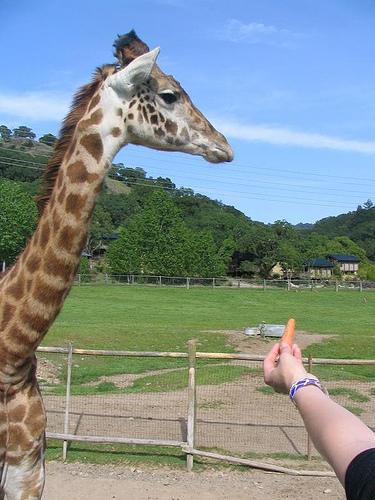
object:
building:
[325, 253, 362, 274]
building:
[303, 256, 335, 277]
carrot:
[278, 318, 295, 354]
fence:
[34, 345, 374, 476]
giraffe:
[0, 28, 234, 499]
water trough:
[244, 321, 286, 338]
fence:
[75, 274, 374, 293]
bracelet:
[289, 377, 328, 408]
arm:
[262, 342, 374, 499]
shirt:
[345, 447, 375, 500]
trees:
[99, 184, 236, 285]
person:
[263, 343, 375, 499]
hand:
[262, 343, 374, 490]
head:
[106, 28, 234, 164]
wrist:
[288, 372, 329, 409]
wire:
[69, 355, 189, 443]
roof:
[303, 259, 334, 267]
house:
[325, 254, 361, 274]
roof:
[325, 253, 361, 261]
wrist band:
[289, 378, 327, 408]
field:
[33, 284, 375, 500]